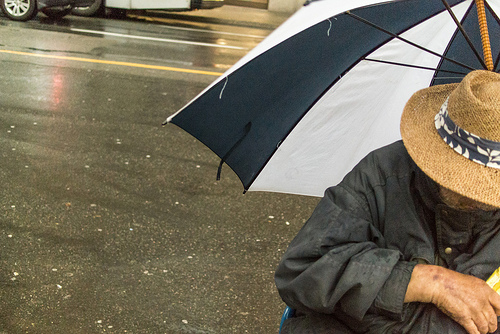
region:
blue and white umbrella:
[157, 0, 499, 212]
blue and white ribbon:
[426, 99, 498, 170]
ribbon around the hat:
[399, 72, 499, 203]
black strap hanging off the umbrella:
[216, 123, 254, 189]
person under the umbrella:
[161, 1, 495, 331]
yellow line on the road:
[0, 45, 227, 112]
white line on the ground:
[71, 23, 246, 52]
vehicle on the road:
[0, 1, 217, 31]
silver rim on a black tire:
[1, 0, 36, 24]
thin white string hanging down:
[319, 17, 336, 38]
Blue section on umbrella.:
[244, 77, 278, 137]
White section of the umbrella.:
[298, 153, 333, 186]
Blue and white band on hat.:
[441, 115, 478, 170]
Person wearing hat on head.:
[413, 128, 433, 155]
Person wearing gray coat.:
[324, 226, 363, 271]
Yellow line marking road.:
[106, 48, 169, 80]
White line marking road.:
[146, 18, 200, 61]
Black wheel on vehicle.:
[7, 4, 42, 22]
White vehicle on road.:
[124, 3, 208, 13]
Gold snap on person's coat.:
[438, 239, 457, 261]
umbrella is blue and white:
[159, 4, 493, 218]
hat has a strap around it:
[409, 61, 496, 182]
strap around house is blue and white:
[429, 85, 499, 181]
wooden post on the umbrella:
[469, 3, 498, 72]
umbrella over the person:
[285, 23, 498, 260]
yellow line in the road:
[9, 35, 205, 95]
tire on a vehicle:
[11, 0, 46, 18]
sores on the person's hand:
[409, 261, 474, 299]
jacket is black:
[269, 110, 499, 332]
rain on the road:
[28, 28, 214, 332]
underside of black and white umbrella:
[158, 0, 498, 197]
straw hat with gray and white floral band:
[401, 68, 498, 206]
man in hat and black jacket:
[267, 69, 498, 331]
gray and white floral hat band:
[431, 94, 498, 167]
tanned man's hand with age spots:
[406, 262, 499, 332]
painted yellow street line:
[1, 47, 226, 76]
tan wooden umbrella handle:
[476, 0, 497, 68]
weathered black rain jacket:
[274, 140, 498, 330]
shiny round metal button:
[444, 245, 454, 254]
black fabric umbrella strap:
[216, 121, 252, 181]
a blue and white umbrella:
[145, 5, 498, 185]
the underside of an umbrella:
[220, 0, 495, 190]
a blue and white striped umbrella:
[152, 6, 499, 188]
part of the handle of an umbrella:
[470, 2, 497, 74]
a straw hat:
[397, 63, 499, 208]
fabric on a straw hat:
[425, 91, 499, 173]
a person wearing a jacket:
[255, 136, 490, 331]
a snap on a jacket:
[442, 244, 454, 256]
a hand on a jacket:
[401, 256, 498, 333]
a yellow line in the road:
[10, 46, 230, 92]